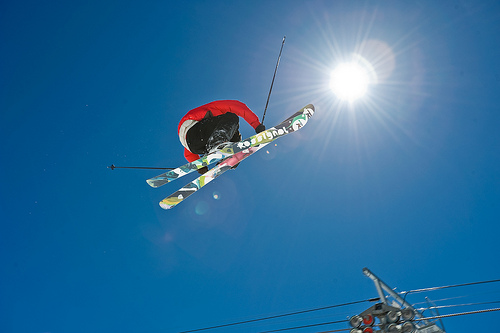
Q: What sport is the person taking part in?
A: Skiing.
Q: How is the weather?
A: Sunny and clear blue skies.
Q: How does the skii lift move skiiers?
A: With the overhanging wires.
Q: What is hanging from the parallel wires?
A: A skiier on a skii lift.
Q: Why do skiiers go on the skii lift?
A: To get to the higher part of the mountain.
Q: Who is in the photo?
A: A skier.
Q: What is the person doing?
A: Skiing.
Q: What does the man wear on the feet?
A: Skis.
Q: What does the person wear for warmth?
A: A red coat.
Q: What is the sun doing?
A: Shining.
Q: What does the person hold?
A: Ski poles.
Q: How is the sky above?
A: Clear and blue.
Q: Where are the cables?
A: Between the rollers.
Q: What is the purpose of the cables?
A: To power the lift.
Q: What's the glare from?
A: Sun.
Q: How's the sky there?
A: Clear.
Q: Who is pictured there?
A: Skier.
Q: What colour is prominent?
A: Red.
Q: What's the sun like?
A: Very bright.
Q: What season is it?
A: Summer.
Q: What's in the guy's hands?
A: Poles.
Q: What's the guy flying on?
A: Skis.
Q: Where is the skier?
A: Mid-air.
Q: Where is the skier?
A: In the air.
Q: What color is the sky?
A: Blue.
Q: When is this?
A: Daytime.